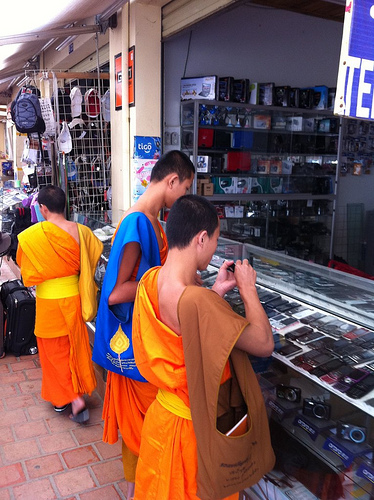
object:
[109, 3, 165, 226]
wall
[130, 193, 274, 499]
man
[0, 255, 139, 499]
floor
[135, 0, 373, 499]
shop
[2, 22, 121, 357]
shop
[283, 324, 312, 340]
mobile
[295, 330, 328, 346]
mobile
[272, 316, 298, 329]
mobile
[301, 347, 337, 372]
mobile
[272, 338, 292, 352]
mobile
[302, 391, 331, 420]
camera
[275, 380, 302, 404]
camera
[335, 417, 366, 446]
camera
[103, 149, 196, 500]
man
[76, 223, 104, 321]
bag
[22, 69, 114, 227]
mesh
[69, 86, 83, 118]
caps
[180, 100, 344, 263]
case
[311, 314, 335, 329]
mobile phones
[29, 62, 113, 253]
rack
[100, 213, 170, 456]
robe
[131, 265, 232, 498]
robe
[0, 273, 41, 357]
suitcase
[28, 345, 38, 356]
wheels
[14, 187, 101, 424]
man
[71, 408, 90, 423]
sandal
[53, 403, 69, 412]
sandal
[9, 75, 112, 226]
merchandise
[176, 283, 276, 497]
bag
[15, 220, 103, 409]
clothes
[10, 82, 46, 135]
backpack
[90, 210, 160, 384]
bag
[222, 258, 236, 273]
camera